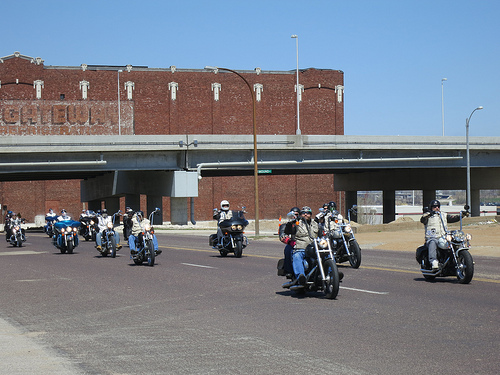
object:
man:
[214, 200, 245, 245]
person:
[419, 199, 474, 269]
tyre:
[443, 249, 484, 287]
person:
[283, 205, 329, 287]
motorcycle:
[2, 213, 28, 247]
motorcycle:
[414, 196, 476, 280]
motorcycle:
[118, 207, 162, 265]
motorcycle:
[84, 208, 122, 255]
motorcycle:
[49, 207, 80, 251]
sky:
[314, 25, 460, 83]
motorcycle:
[273, 200, 345, 293]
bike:
[207, 207, 247, 255]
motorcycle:
[322, 205, 365, 268]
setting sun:
[203, 194, 255, 261]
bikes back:
[415, 246, 442, 278]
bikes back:
[277, 260, 305, 290]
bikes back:
[210, 233, 227, 255]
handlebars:
[424, 199, 476, 241]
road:
[0, 224, 493, 374]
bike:
[120, 193, 162, 268]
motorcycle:
[205, 211, 250, 258]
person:
[123, 209, 163, 264]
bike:
[268, 217, 339, 296]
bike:
[412, 212, 477, 285]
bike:
[3, 209, 29, 252]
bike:
[52, 209, 82, 251]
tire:
[447, 247, 475, 286]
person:
[204, 197, 238, 244]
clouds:
[69, 18, 192, 48]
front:
[302, 231, 339, 294]